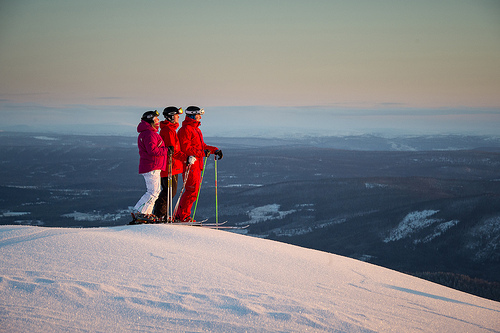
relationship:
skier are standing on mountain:
[128, 112, 166, 224] [1, 224, 498, 329]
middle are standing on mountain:
[152, 106, 198, 224] [1, 224, 498, 329]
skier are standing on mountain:
[176, 105, 224, 225] [1, 224, 498, 329]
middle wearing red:
[152, 106, 198, 224] [159, 123, 183, 174]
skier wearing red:
[176, 105, 224, 225] [174, 120, 214, 225]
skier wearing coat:
[128, 112, 166, 224] [137, 122, 169, 176]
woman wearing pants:
[128, 112, 166, 224] [136, 167, 163, 215]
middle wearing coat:
[152, 106, 198, 224] [159, 120, 187, 176]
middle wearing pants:
[152, 106, 198, 224] [155, 170, 178, 219]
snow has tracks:
[1, 224, 498, 329] [13, 271, 352, 330]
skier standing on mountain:
[128, 112, 166, 224] [1, 224, 498, 329]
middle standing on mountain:
[152, 106, 198, 224] [1, 224, 498, 329]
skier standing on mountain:
[176, 105, 224, 225] [1, 224, 498, 329]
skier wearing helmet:
[128, 112, 166, 224] [141, 110, 159, 126]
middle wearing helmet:
[152, 106, 198, 224] [163, 105, 181, 120]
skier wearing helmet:
[176, 105, 224, 225] [186, 104, 197, 122]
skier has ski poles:
[128, 112, 166, 224] [166, 146, 174, 225]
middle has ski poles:
[152, 106, 198, 224] [171, 158, 197, 222]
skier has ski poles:
[176, 105, 224, 225] [192, 152, 224, 226]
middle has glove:
[152, 106, 198, 224] [188, 154, 195, 165]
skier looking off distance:
[128, 112, 166, 224] [221, 138, 499, 286]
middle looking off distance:
[152, 106, 198, 224] [221, 138, 499, 286]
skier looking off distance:
[176, 105, 224, 225] [221, 138, 499, 286]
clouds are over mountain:
[13, 102, 495, 131] [1, 224, 498, 329]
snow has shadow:
[1, 224, 498, 329] [2, 225, 171, 256]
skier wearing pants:
[176, 105, 224, 225] [174, 153, 204, 227]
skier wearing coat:
[176, 105, 224, 225] [177, 116, 216, 170]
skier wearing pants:
[128, 112, 166, 224] [136, 167, 163, 215]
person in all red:
[176, 105, 224, 225] [174, 120, 214, 225]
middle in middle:
[152, 106, 198, 224] [151, 96, 185, 219]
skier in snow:
[128, 112, 166, 224] [1, 224, 498, 329]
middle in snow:
[152, 106, 198, 224] [1, 224, 498, 329]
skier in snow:
[176, 105, 224, 225] [1, 224, 498, 329]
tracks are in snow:
[13, 271, 352, 330] [1, 224, 498, 329]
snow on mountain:
[1, 224, 498, 329] [1, 224, 498, 329]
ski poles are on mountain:
[166, 146, 174, 225] [1, 224, 498, 329]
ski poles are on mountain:
[171, 158, 197, 222] [1, 224, 498, 329]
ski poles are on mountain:
[192, 152, 224, 226] [1, 224, 498, 329]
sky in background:
[1, 1, 498, 113] [0, 1, 495, 324]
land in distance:
[0, 130, 498, 295] [221, 138, 499, 286]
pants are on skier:
[136, 167, 163, 215] [128, 112, 166, 224]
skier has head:
[128, 112, 166, 224] [144, 106, 161, 129]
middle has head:
[152, 106, 198, 224] [165, 106, 179, 123]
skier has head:
[176, 105, 224, 225] [190, 109, 200, 123]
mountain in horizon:
[1, 102, 497, 142] [0, 105, 497, 141]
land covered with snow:
[0, 130, 498, 295] [1, 171, 450, 259]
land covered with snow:
[0, 130, 498, 295] [1, 224, 498, 329]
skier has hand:
[128, 112, 166, 224] [163, 142, 177, 155]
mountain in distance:
[1, 102, 497, 142] [221, 138, 499, 286]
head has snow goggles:
[144, 106, 161, 129] [149, 111, 160, 120]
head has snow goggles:
[165, 106, 179, 123] [169, 104, 184, 118]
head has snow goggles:
[190, 109, 200, 123] [187, 109, 204, 117]